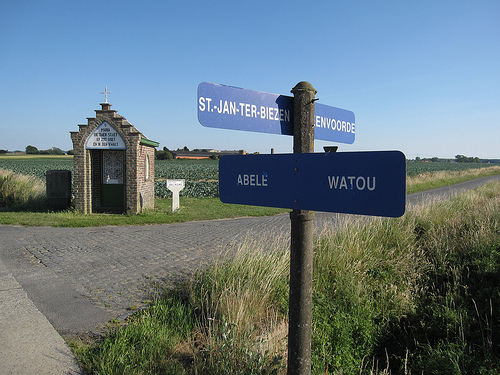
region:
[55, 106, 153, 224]
brown building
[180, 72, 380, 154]
blue and white sign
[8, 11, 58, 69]
white clouds in blue sky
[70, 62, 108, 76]
white clouds in blue sky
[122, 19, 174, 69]
white clouds in blue sky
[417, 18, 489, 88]
white clouds in blue sky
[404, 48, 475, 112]
white clouds in blue sky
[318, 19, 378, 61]
white clouds in blue sky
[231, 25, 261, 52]
white clouds in blue sky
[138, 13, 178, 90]
white clouds in blue sky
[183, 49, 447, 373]
Blue signs on the pole.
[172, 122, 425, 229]
White letters on the blue sign.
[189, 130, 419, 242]
Words on the blue sign.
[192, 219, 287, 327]
Grass by the road.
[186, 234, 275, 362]
Tall grass by the road.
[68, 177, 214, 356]
Road between the grasses.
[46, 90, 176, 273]
Brick building by the road.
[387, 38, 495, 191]
Blue sky in the background.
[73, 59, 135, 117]
Cross on the building.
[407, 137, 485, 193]
Trees in the background.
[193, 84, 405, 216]
Blue signs by the road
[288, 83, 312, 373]
A pole connected to the blue signs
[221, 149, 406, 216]
The sign is rectangular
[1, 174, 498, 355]
A street near the farm field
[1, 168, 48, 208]
Bushes by the side of the road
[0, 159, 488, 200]
A farm field near the road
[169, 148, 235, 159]
A building beyond the farm field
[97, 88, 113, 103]
A cross on top of the building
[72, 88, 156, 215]
A religious building near the road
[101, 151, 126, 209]
A door on the religious building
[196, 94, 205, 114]
The letter is white.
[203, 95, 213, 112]
The letter is white.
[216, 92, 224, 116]
The letter is white.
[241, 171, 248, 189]
The letter is white.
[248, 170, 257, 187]
The letter is white.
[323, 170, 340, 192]
The letter is white.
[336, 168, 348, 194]
The letter is white.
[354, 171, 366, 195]
The letter is white.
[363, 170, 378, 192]
The letter is white.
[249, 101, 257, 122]
The letter is white.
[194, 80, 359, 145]
blue and white street sign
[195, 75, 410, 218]
two blue and white street signs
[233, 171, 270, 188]
white print on a blue sign reading Abele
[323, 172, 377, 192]
white print on a sign reading Watou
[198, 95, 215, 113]
white print on a sign reading ST.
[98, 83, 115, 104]
white cross on a small structure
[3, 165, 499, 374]
long empty road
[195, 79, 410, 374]
two street signs on a pole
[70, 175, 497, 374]
lots of tall gras along a path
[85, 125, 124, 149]
black lettering on a structure